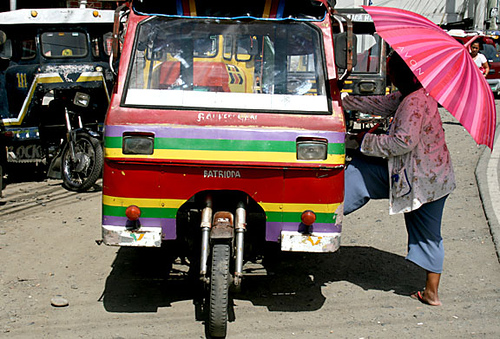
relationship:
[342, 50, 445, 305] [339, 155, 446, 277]
woman wearing blue pants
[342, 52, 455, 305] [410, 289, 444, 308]
woman wearing flip flop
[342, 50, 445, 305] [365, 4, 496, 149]
woman holding umbrella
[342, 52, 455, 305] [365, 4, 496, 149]
woman holding umbrella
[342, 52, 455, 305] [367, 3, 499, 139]
woman carrying umbrella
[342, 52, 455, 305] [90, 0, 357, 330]
woman climbing into vehicle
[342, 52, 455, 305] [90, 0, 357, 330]
woman getting in vehicle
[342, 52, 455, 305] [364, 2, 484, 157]
woman has umbrella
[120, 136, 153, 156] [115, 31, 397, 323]
headlight of cab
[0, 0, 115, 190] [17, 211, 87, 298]
cabs on street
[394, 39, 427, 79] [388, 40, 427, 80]
letters read avon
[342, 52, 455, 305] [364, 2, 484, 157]
woman holding umbrella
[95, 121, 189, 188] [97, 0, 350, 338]
headlight in front of cab